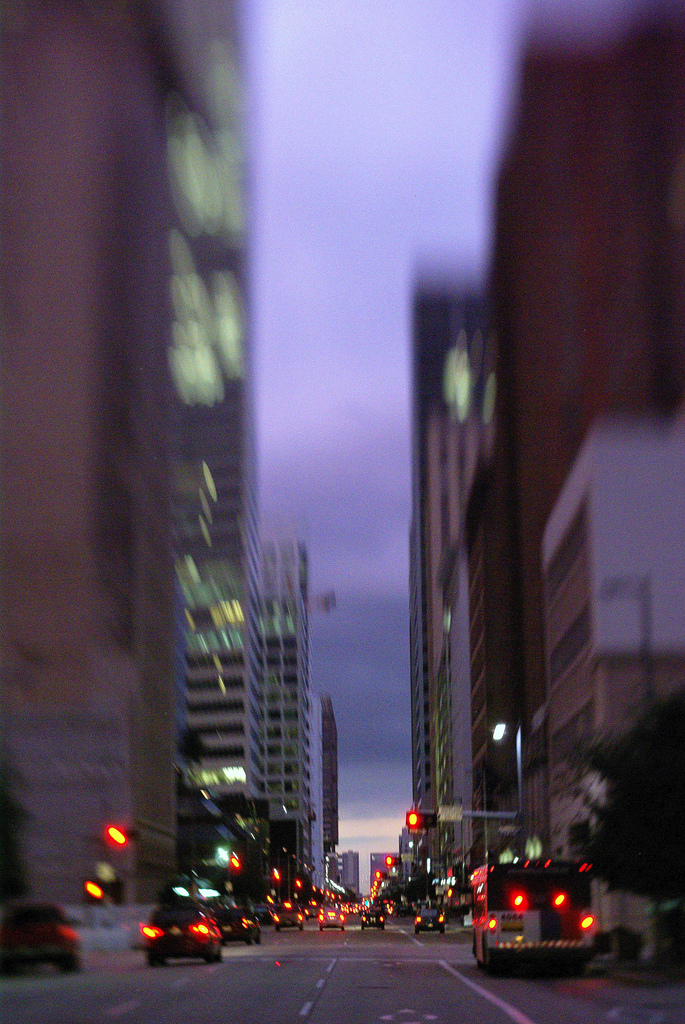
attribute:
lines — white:
[236, 942, 380, 1009]